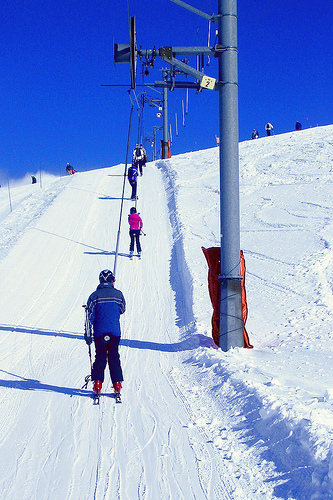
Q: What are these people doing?
A: Skiing.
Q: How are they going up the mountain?
A: Ski lift.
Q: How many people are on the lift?
A: 4.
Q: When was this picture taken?
A: Daytime.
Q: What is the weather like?
A: Cold and sunny.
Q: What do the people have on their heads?
A: Helmets.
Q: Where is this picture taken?
A: Ski mountain.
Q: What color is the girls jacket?
A: Pink.